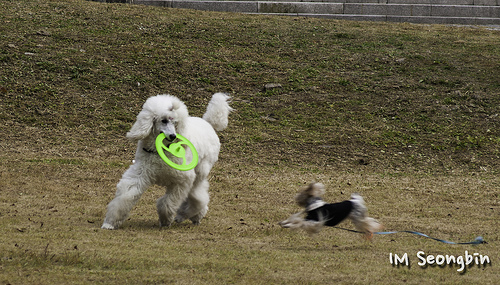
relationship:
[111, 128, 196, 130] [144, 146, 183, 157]
dog carrying frisbee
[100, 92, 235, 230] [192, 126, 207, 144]
dog a color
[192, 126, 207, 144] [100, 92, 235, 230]
color on dog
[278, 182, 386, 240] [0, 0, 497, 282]
dog running on ground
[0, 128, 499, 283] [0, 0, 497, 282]
dirt on ground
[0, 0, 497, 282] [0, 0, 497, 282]
grass on ground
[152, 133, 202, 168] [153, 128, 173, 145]
frisbee in mouth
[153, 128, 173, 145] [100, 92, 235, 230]
mouth on dog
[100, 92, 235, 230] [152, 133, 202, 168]
dog has frisbee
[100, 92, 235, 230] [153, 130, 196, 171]
dog carrying frisbee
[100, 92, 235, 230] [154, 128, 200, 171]
dog carrying frisbee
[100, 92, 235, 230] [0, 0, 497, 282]
dog on grass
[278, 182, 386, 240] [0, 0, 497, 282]
dog on grass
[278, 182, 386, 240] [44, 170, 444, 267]
dog playing on grass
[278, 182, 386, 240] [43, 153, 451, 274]
dog playing on grass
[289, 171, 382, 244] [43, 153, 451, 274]
dog playing on grass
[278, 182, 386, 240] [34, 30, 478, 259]
dog running in park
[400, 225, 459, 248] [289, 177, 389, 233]
leash on dog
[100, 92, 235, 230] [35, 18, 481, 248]
dog in park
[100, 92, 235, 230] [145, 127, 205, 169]
dog holding frisbee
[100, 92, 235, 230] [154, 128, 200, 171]
dog with frisbee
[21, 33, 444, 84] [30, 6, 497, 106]
grass growing on hill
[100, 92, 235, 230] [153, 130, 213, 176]
dog holding frisbee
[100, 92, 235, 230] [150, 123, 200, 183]
dog holding frisbee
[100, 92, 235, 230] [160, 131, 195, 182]
dog holding frisbee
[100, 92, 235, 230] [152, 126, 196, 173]
dog holding frisbee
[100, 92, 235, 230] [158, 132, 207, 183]
dog holding frisbee